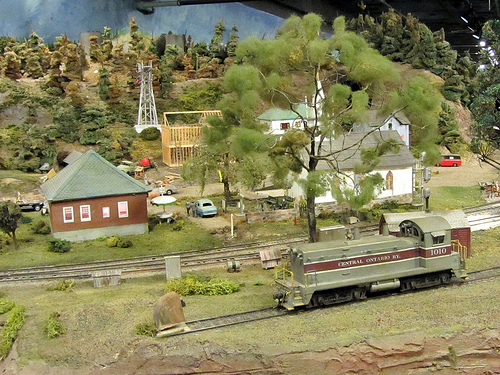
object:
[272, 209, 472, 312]
train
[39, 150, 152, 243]
house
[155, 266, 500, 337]
spur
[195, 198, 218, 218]
car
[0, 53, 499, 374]
ground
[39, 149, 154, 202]
roof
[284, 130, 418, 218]
church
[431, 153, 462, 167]
van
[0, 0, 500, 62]
sky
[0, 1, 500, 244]
trees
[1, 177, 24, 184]
stone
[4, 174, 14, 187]
edge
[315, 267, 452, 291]
edge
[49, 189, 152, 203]
edge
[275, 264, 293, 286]
part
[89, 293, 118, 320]
part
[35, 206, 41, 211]
wheel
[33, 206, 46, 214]
part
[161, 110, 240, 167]
frame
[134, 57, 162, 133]
tower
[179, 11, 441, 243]
oak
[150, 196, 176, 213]
umbrella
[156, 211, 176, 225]
table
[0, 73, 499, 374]
town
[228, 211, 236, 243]
post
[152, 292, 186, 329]
stop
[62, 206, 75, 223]
windows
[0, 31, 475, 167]
hill